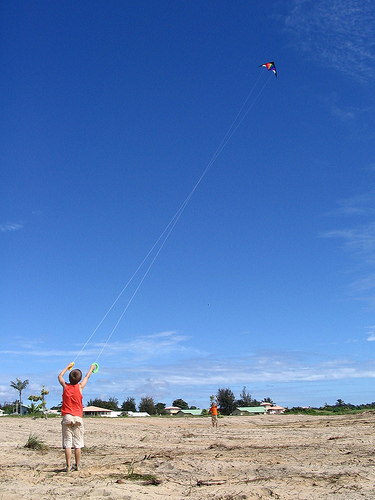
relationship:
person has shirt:
[63, 356, 93, 479] [63, 388, 81, 413]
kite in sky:
[257, 44, 286, 82] [254, 51, 288, 92]